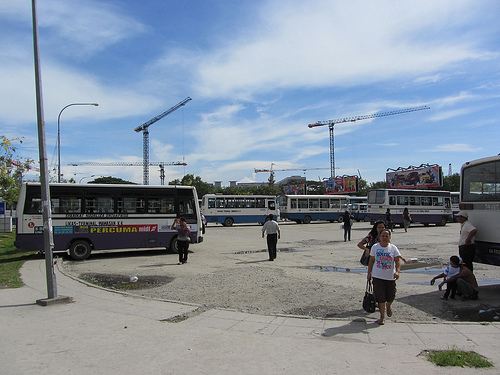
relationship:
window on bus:
[274, 195, 292, 214] [282, 189, 362, 225]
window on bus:
[454, 147, 496, 217] [445, 138, 496, 268]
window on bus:
[461, 160, 500, 200] [440, 144, 499, 287]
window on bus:
[387, 188, 413, 210] [366, 173, 460, 234]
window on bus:
[407, 188, 428, 208] [360, 182, 462, 230]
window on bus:
[425, 192, 454, 210] [360, 182, 462, 230]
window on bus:
[425, 192, 454, 210] [365, 180, 465, 231]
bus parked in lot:
[11, 176, 211, 275] [4, 165, 495, 374]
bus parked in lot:
[200, 183, 288, 237] [4, 165, 495, 374]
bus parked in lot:
[278, 187, 360, 226] [4, 165, 495, 374]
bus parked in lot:
[364, 176, 460, 231] [4, 165, 495, 374]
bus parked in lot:
[449, 149, 499, 292] [4, 165, 495, 374]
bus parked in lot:
[272, 187, 287, 217] [4, 165, 495, 374]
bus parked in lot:
[346, 188, 373, 224] [4, 165, 495, 374]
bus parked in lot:
[446, 183, 494, 221] [4, 165, 495, 374]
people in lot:
[167, 211, 437, 304] [272, 274, 291, 284]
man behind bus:
[453, 210, 479, 281] [428, 156, 497, 241]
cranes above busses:
[138, 79, 400, 194] [166, 173, 408, 217]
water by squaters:
[395, 254, 440, 282] [437, 249, 472, 300]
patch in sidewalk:
[421, 345, 492, 372] [255, 323, 365, 365]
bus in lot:
[277, 194, 353, 225] [203, 257, 291, 301]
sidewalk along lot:
[112, 294, 190, 340] [190, 276, 247, 296]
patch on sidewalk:
[421, 334, 481, 372] [290, 331, 335, 350]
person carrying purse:
[365, 231, 400, 321] [359, 294, 372, 314]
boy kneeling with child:
[437, 263, 477, 298] [439, 254, 458, 293]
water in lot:
[395, 254, 440, 282] [166, 257, 261, 304]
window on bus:
[55, 193, 79, 213] [8, 169, 226, 261]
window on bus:
[93, 197, 118, 215] [35, 187, 155, 232]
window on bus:
[283, 194, 317, 215] [284, 182, 367, 232]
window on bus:
[300, 193, 332, 212] [288, 193, 351, 224]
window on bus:
[320, 198, 330, 213] [279, 177, 359, 225]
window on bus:
[300, 193, 332, 212] [280, 198, 334, 222]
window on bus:
[387, 188, 413, 210] [367, 187, 452, 222]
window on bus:
[398, 193, 415, 206] [367, 186, 463, 226]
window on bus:
[407, 188, 428, 208] [361, 186, 457, 224]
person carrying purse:
[365, 231, 400, 321] [364, 281, 374, 314]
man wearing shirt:
[261, 214, 282, 259] [263, 219, 279, 233]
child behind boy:
[428, 254, 459, 293] [447, 263, 478, 298]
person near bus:
[398, 207, 410, 227] [367, 186, 453, 228]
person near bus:
[381, 206, 393, 226] [367, 186, 453, 228]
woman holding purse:
[360, 222, 381, 293] [358, 243, 371, 266]